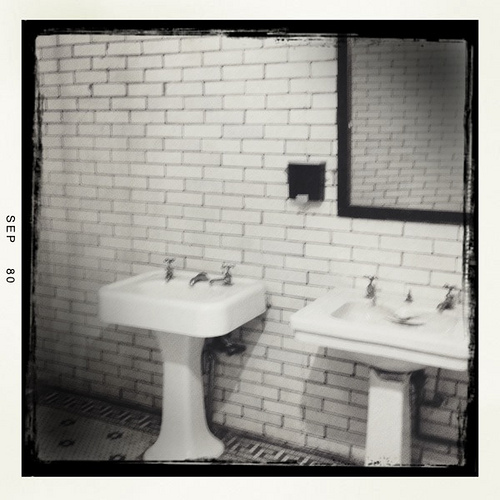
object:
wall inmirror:
[335, 35, 476, 225]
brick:
[221, 208, 262, 225]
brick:
[72, 43, 107, 58]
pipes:
[216, 337, 247, 357]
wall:
[31, 29, 473, 466]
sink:
[287, 286, 469, 374]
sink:
[99, 269, 268, 460]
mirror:
[347, 38, 469, 213]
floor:
[28, 387, 356, 468]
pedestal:
[142, 331, 225, 463]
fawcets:
[162, 256, 236, 289]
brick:
[182, 124, 223, 140]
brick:
[221, 153, 265, 169]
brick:
[144, 67, 182, 84]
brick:
[304, 243, 352, 263]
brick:
[66, 210, 98, 224]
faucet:
[188, 272, 208, 288]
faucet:
[403, 288, 414, 303]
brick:
[279, 389, 323, 413]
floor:
[167, 217, 204, 234]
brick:
[264, 267, 308, 287]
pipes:
[423, 393, 443, 408]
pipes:
[202, 350, 217, 426]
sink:
[112, 272, 245, 305]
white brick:
[402, 237, 461, 256]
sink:
[288, 285, 466, 469]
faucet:
[163, 257, 176, 283]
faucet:
[208, 262, 235, 287]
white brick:
[163, 53, 203, 68]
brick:
[245, 109, 289, 126]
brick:
[60, 57, 92, 72]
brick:
[201, 138, 242, 154]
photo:
[35, 34, 466, 466]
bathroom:
[37, 32, 475, 465]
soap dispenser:
[284, 162, 326, 202]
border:
[19, 21, 479, 477]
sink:
[335, 298, 465, 344]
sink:
[97, 268, 267, 340]